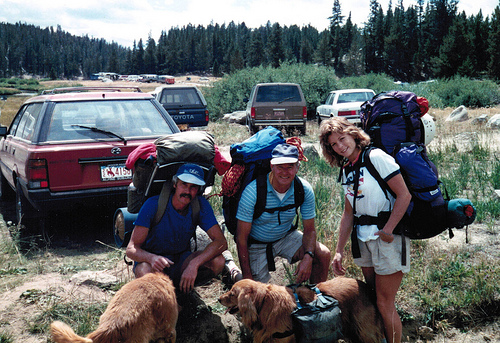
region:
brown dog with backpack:
[216, 277, 384, 342]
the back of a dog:
[48, 268, 181, 341]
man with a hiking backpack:
[113, 129, 228, 303]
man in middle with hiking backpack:
[223, 123, 331, 298]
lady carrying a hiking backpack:
[314, 90, 476, 335]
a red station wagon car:
[0, 93, 202, 235]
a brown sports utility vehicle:
[246, 80, 308, 133]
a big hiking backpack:
[357, 89, 477, 237]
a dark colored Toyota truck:
[143, 83, 210, 135]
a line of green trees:
[6, 0, 494, 85]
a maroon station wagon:
[0, 86, 202, 236]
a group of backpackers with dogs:
[36, 86, 481, 341]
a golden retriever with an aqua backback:
[215, 274, 393, 341]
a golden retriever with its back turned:
[41, 272, 186, 341]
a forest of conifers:
[1, 0, 498, 90]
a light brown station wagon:
[241, 79, 316, 134]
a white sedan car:
[317, 86, 382, 127]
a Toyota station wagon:
[152, 81, 217, 130]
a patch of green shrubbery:
[200, 58, 497, 125]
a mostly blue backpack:
[353, 86, 482, 241]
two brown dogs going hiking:
[48, 271, 380, 341]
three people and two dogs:
[47, 89, 476, 341]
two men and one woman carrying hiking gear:
[112, 90, 475, 340]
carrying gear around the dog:
[287, 280, 345, 341]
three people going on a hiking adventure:
[47, 88, 477, 341]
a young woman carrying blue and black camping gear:
[318, 89, 475, 341]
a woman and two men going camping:
[47, 88, 477, 341]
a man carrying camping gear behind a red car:
[2, 87, 227, 342]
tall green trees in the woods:
[0, 1, 498, 78]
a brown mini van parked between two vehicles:
[247, 81, 308, 127]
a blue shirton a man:
[132, 194, 219, 262]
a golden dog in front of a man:
[43, 266, 184, 342]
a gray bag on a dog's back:
[288, 282, 349, 342]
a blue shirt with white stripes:
[236, 175, 318, 248]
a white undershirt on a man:
[273, 188, 288, 202]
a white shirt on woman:
[336, 145, 403, 247]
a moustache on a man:
[177, 191, 194, 199]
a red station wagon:
[0, 89, 191, 242]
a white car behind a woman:
[316, 83, 377, 130]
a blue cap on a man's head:
[170, 161, 207, 183]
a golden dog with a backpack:
[225, 273, 388, 341]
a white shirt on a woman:
[338, 144, 400, 244]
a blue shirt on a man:
[128, 195, 220, 258]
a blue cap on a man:
[170, 164, 210, 188]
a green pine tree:
[143, 34, 157, 74]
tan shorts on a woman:
[350, 230, 411, 279]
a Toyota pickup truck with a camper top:
[148, 80, 216, 134]